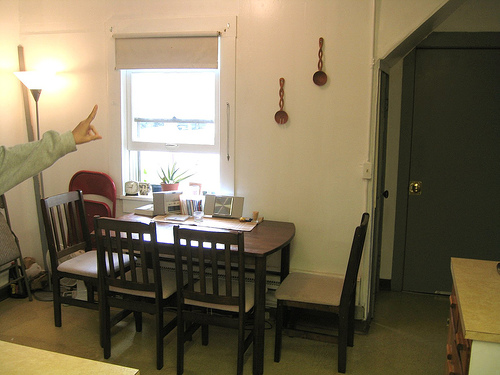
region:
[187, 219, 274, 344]
a chair under table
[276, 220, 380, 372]
a chair under table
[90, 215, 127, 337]
a chair under the table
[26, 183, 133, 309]
a chair under the table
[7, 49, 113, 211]
a tall standing lamp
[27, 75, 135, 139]
the person is pointing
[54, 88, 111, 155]
these are fingers on a hand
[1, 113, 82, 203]
the sleeve is gray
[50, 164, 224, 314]
this is a dining room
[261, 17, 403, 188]
the spoons are hanging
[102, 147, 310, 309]
this is a table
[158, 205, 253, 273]
the table is wood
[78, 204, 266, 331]
the chairs are wood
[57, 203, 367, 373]
the chairs are in four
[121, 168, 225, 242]
the table top is cluttered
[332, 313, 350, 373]
the leg of a chair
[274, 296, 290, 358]
the leg of a chair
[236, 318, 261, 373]
the leg of a chair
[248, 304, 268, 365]
the leg of a chair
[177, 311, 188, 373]
the leg of a chair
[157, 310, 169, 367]
the leg of a chair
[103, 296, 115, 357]
the leg of a chair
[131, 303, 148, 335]
the leg of a chair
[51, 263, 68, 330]
the leg of a chair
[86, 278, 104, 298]
the leg of a chair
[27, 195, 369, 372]
wood table with four chairs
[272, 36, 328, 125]
two spoons hanging on the wall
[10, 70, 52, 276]
floor lamp with a white glass shade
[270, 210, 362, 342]
chair sitting at the head of the table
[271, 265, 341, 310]
seat of the wood chair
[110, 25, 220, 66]
taupe colored window shade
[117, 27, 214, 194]
window in the room with the table and chairs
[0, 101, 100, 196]
man's left arm extended while pointing his finger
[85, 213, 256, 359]
two chairs on the side of the wood table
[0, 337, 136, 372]
white top of a cabinet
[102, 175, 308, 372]
this is a table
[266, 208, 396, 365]
this is a chair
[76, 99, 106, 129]
this is a finger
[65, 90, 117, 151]
the finger is extended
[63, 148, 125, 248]
a red folded chair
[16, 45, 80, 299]
a tall floor lamp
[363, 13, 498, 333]
this is a door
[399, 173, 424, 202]
this is a door knob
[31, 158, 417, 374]
wooden table and chairs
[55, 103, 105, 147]
FInger pointing in the air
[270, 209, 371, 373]
Chair pulled out from table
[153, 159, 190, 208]
Aloe plant on the windowsill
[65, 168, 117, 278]
Folding chair leaning against wall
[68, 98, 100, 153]
Hand with pointing finger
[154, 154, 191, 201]
Aloe plant on the windowsill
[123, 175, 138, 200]
Clock on the windowsill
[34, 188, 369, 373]
Table and chairs in front of the window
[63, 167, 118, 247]
Folding chair to the left of the window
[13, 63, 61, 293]
Lit floor lamp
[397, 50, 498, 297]
Green door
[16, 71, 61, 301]
a lit floor lamp